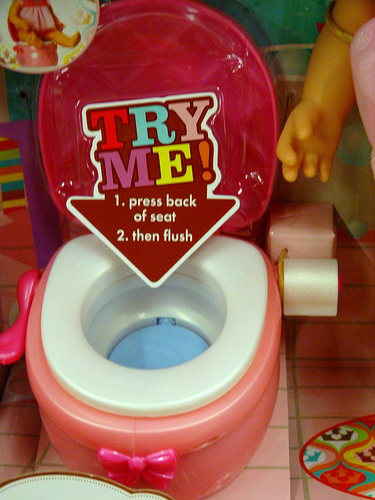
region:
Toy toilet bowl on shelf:
[24, 136, 253, 469]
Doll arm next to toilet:
[251, 46, 352, 197]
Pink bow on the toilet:
[100, 429, 155, 493]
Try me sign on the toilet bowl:
[64, 90, 222, 283]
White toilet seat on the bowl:
[61, 260, 240, 413]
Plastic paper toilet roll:
[265, 256, 344, 334]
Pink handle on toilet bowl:
[9, 262, 33, 376]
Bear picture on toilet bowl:
[8, 4, 95, 84]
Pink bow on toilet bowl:
[67, 379, 194, 499]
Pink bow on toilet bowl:
[90, 430, 193, 498]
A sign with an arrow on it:
[62, 98, 246, 287]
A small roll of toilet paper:
[281, 253, 340, 325]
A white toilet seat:
[43, 230, 269, 418]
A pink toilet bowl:
[11, 248, 311, 497]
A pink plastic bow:
[94, 440, 179, 496]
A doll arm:
[271, 0, 373, 186]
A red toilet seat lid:
[40, 0, 280, 243]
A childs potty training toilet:
[11, 7, 312, 494]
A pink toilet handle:
[0, 266, 43, 376]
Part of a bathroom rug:
[292, 408, 373, 496]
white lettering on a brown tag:
[109, 189, 194, 246]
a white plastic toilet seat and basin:
[61, 231, 249, 423]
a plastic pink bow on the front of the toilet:
[91, 441, 181, 490]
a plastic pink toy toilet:
[12, 236, 280, 472]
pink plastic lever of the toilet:
[0, 255, 37, 369]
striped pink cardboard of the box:
[294, 334, 369, 395]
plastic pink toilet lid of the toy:
[41, 6, 272, 225]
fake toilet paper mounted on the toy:
[278, 252, 347, 325]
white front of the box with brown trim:
[0, 470, 196, 498]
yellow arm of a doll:
[265, 21, 374, 173]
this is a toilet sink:
[47, 271, 252, 407]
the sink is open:
[51, 269, 264, 400]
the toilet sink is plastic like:
[49, 270, 262, 428]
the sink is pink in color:
[207, 399, 262, 465]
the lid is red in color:
[92, 23, 235, 178]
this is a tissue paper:
[282, 255, 338, 317]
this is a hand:
[286, 54, 348, 171]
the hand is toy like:
[317, 45, 349, 114]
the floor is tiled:
[261, 459, 285, 498]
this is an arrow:
[82, 99, 217, 255]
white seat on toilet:
[55, 243, 238, 434]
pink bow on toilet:
[97, 440, 177, 493]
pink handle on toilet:
[1, 263, 41, 349]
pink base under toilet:
[227, 398, 308, 497]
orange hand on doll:
[258, 2, 372, 162]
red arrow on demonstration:
[77, 98, 220, 286]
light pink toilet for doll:
[26, 265, 283, 494]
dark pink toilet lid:
[53, 24, 279, 235]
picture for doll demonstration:
[16, 0, 88, 68]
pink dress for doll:
[333, 32, 373, 103]